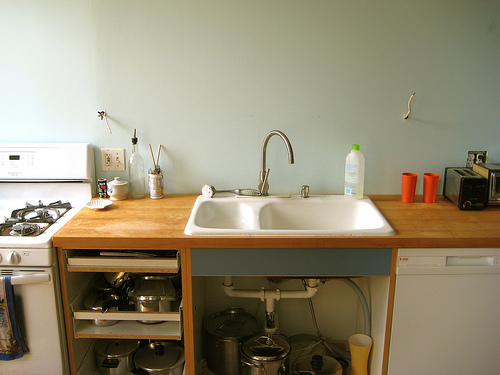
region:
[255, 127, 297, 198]
curved faucet on sink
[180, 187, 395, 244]
white porcelain kitchen sink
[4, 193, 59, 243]
burners on gas stove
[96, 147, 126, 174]
electrical outlet near stove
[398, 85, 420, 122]
wire hanging out of wall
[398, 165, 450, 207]
two orange cups on counter top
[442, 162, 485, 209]
two slice toaster that is black and silver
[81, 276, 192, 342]
pots and pans in cabinet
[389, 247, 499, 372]
white built in dishwasher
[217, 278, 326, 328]
drain pipes under sink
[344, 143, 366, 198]
A bottle of soap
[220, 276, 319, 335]
A white pipe for a sink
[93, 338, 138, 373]
A metal pot in a cabinet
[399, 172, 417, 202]
An orange plastic cup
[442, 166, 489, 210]
A metal toaster on a counter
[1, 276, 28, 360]
A towel on a handle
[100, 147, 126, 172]
A receptacle outlet on a wall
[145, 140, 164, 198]
A container on a counter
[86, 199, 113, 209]
A small dish on a counter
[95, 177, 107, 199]
A black pepper shaker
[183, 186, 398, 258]
white sink in a kitchen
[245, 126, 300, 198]
faucet of a sink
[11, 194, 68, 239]
burners on a stove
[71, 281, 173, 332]
pots in a cabinet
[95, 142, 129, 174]
outlet on a wall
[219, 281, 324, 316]
pipes under a sink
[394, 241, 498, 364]
dishwasher in a sink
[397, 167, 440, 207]
cups on a counter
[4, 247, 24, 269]
knob on a stove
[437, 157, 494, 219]
toaster on a counter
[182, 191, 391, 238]
a large white kitchen sink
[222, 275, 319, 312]
a white pipe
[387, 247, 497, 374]
part of a white dishwasher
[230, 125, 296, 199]
a kitchen sink faucet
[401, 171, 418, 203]
an orange cup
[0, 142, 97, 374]
part of a white oven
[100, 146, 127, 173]
a white wall outlet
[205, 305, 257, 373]
a large gray pot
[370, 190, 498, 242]
part of a brown counter top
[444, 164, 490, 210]
a gray and black toaster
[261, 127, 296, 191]
large silver faucet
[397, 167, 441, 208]
two orange cups on the counter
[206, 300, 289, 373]
silver pots under the sink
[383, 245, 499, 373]
white dishwasher built into the counter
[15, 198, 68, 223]
black burner on the stovetop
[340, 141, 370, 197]
clear bottle with a green cap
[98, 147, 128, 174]
outlet on the wall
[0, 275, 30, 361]
towel hanging on the oven door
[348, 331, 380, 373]
bright yellow cup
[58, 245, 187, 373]
no door on the cabinet